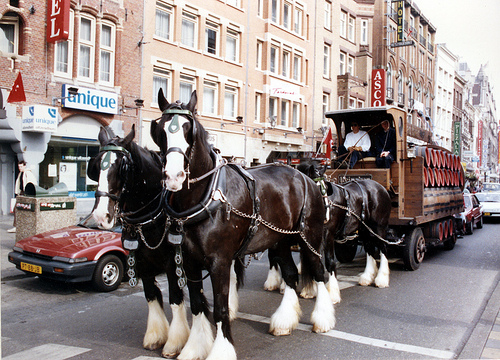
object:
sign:
[395, 0, 404, 44]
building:
[373, 0, 438, 143]